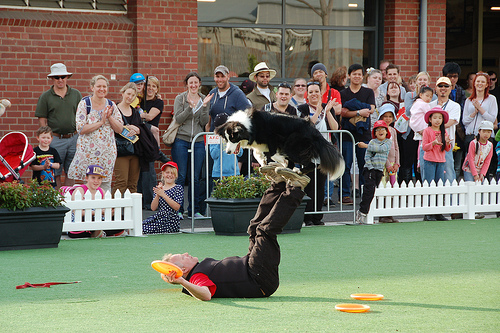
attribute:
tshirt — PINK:
[425, 129, 445, 161]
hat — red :
[423, 105, 447, 124]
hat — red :
[160, 159, 177, 169]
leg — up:
[245, 179, 284, 255]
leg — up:
[248, 185, 307, 285]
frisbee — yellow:
[147, 254, 189, 283]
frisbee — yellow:
[331, 292, 363, 309]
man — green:
[35, 70, 120, 168]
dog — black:
[214, 104, 344, 187]